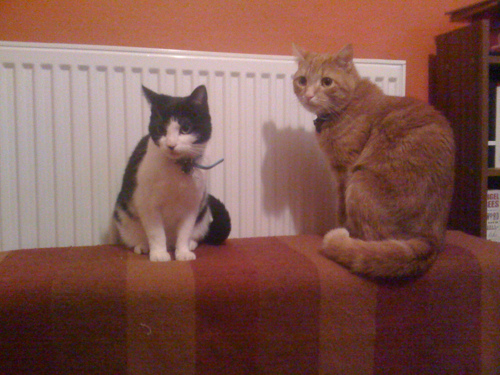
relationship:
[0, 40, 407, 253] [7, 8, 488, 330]
back rest on wall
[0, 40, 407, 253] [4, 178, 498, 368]
back rest behind ottoman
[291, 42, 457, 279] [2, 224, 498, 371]
brown cat on ottoman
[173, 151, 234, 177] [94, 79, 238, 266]
collar on cat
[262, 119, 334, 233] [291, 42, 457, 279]
shadow of brown cat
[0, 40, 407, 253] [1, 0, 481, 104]
back rest on wall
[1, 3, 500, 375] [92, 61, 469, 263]
wall behind cats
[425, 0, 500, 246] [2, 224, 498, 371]
book shelf beside ottoman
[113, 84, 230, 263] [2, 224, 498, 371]
cat sitting on ottoman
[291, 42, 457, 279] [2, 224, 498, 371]
brown cat sitting on ottoman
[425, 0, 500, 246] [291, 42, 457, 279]
book shelf beside brown cat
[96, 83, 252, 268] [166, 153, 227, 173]
cat wearing collar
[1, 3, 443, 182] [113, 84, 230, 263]
wall behind cat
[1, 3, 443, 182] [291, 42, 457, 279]
wall behind brown cat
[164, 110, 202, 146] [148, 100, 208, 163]
markings on face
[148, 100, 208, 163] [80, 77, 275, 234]
face of cat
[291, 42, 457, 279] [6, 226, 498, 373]
brown cat sitting on bench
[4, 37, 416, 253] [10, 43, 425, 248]
back of bench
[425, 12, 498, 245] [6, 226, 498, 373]
book shelf beside bench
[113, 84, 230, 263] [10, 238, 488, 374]
cat sitting on chair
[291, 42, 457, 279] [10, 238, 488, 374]
brown cat sitting on chair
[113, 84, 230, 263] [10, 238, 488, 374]
cat on chair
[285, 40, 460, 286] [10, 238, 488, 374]
brown cat sitting in chair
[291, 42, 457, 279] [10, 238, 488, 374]
brown cat sitting in chair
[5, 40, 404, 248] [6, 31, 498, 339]
back rest of chair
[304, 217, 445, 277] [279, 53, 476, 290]
tail of cat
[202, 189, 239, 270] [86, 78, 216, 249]
tail of cat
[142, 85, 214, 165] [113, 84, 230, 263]
head of cat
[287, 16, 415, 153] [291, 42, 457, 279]
head of brown cat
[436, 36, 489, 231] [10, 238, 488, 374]
cabinet door next to chair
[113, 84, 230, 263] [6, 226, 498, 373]
cat on bench